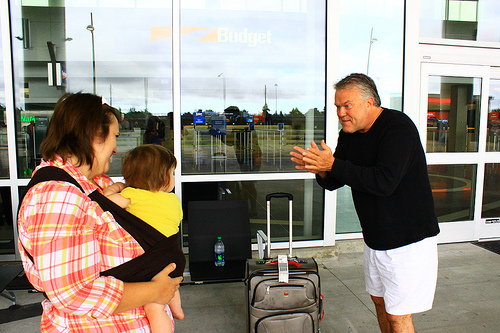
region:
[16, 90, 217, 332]
Woman in red, yellow, and white plaid shirt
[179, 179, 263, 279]
Black luggage bag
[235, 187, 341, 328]
Grey and black luggage bag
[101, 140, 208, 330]
baby in yellow shirt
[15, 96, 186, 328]
woman holding small baby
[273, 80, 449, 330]
man cheering on to baby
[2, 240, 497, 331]
Grey colored cement floor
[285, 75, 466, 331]
Old man clapping hands together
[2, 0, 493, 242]
Glass windows and doors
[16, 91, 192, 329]
old woman holding on to baby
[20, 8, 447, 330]
family getting ready to travel together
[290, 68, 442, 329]
happy man trying to play with baby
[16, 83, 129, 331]
mom smiling at happy man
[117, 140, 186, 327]
baby observing happy man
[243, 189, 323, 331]
grey and black suitcase for travel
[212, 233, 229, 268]
dasani water bottle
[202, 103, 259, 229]
reflection of happy man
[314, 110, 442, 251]
black long sleeved shirt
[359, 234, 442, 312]
white shorts on happy man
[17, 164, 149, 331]
orange plaid and white shirt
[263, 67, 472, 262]
the man is clapping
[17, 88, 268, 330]
woman carrying baby in sling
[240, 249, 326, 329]
the suitcase is gray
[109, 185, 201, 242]
baby's shirt is yellow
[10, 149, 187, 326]
woman's shirt is plaid patterned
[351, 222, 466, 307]
man's shorts are white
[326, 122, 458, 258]
man's shirt is black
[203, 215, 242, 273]
water bottle on object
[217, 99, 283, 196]
reflection of man in window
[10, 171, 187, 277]
the sling is brown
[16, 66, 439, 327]
man, woman and child interacting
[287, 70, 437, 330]
man clapping his hands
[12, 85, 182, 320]
mother carrying child in body sling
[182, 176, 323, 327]
black and gray luggage on ground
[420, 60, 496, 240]
door with glass panels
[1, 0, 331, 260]
glass windows in metal frame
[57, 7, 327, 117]
clouds and sky reflected in windows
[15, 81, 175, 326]
woman in orange and yellow plaid shirt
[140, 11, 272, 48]
company name and logo on window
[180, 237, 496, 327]
blotchy grey pavement in front of business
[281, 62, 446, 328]
This is a person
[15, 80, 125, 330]
This is a person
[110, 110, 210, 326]
This is a person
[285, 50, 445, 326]
This is a man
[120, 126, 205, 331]
This is a child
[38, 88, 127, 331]
This is a woman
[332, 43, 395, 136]
Head of a man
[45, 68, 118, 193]
Head of a woman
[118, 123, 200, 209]
Head of a child